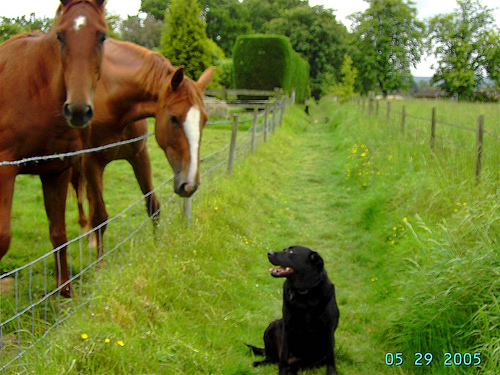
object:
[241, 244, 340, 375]
dog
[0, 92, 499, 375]
grass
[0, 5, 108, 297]
horse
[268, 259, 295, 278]
mouth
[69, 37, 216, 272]
horse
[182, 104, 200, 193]
spot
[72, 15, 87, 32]
spot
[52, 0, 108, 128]
head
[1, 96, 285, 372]
fence